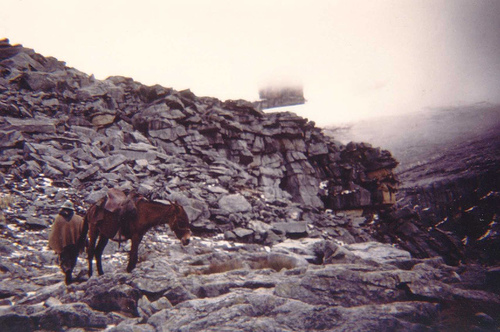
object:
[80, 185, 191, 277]
horse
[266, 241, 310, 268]
rock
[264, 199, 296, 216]
rock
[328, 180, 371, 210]
rock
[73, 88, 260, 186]
rock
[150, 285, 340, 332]
rock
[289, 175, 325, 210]
rock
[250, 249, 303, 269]
rock